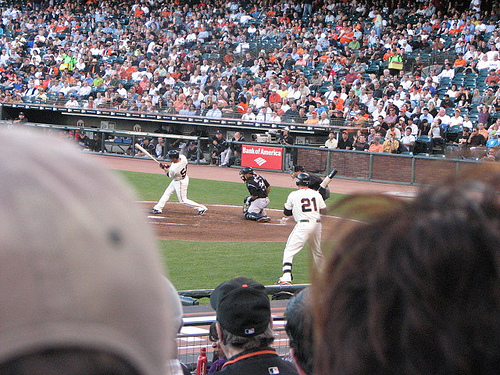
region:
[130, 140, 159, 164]
a brown baseball bat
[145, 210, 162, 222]
part of a white base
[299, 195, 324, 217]
the player's team number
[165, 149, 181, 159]
a black helmet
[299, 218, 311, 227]
part of a man's black belt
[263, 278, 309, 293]
part of a black rail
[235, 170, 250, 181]
a face mask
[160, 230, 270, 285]
a portion of green grass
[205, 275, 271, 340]
a black baseball cap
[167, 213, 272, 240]
a section of brown dirt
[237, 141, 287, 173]
red and white sign on fence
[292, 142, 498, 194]
red and brown brick wall around baseball field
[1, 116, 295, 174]
chain-link fence around baseball field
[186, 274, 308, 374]
man wearing black and orange hat watching baseball game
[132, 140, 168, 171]
light brown wooden bat in batter's hands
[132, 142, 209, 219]
batter in white uniform swinging bat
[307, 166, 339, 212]
black wooden bat with white weight on it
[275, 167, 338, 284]
batter waiting for his turn to bat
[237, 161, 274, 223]
catcher kneeling and waiting to catch baseball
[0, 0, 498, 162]
large crowd of fans sitting in stands watching baseball game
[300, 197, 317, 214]
The number 21 on the player's shirt.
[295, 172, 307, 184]
The black helmet on player 21's head.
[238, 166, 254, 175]
The helmet on the catcher.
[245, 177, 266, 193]
The black shirt the catcher is wearing.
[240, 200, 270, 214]
The white pants the catcher is wearing.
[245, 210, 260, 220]
The knee guard shield on the catcher's right leg.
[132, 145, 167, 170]
The bat in the batter's hand.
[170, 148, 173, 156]
The black helmet on the batter's head.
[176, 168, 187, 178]
The number 5 on the batter's shirt.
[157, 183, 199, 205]
The pants the batter is wearing.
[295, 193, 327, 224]
21 on the jersey.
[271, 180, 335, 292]
The uniform is white.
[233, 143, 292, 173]
Bank of America on the sign.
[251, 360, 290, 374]
Baseball logo on the shirt.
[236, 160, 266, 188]
The catcher is wearing a helmet.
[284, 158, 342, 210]
Umpire behind the catcher.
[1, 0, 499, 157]
Spectators in the stand.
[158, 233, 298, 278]
The grass is green.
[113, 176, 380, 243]
There are white lines on the ground.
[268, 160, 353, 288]
this is a man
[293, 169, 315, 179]
this is a helmet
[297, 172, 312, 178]
the helmet is black in color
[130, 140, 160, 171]
this is the bat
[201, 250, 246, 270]
this is a grass area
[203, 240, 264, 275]
the grass is green in color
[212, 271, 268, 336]
this is a cap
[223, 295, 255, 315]
the cap is black in color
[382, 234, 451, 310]
this is the hair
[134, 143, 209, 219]
baseball player is swinging a bat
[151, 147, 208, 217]
baseball player is wearing a batting helmet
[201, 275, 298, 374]
man is wearing a black baseball cap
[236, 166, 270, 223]
catcher is wearing a black helmet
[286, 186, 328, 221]
number 21 on the back of the white shirt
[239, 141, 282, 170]
red sign has white letters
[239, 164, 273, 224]
catcher is wearing a black shirt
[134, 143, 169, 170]
bat is white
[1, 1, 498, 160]
fans sitting in the bleachers